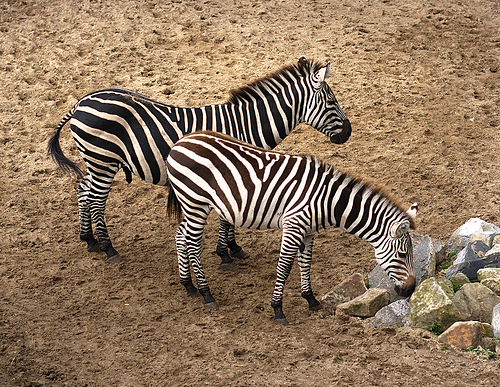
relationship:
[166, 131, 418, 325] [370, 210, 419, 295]
he with head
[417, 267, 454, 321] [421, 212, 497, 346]
moss on rocks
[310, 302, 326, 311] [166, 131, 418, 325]
hoof on he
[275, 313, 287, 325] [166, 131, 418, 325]
hoof on he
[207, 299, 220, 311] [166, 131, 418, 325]
hoof on he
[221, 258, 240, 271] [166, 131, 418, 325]
hoof on he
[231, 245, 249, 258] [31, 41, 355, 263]
hoof on zebra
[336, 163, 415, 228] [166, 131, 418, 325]
mane on he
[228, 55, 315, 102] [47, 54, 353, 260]
mane on zebra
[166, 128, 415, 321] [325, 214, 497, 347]
he looking at rocks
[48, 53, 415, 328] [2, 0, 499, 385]
they standing in field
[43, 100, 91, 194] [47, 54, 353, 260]
tail on zebra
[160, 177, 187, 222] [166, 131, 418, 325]
tail on he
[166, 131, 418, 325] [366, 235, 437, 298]
he smelling rock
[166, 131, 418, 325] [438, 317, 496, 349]
he smelling rock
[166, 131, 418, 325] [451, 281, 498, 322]
he smelling rock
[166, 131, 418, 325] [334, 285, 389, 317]
he smelling rock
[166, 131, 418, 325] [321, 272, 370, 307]
he smelling rock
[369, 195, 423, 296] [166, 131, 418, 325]
head on a he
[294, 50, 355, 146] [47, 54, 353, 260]
head on a zebra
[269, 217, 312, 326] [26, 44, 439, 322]
leg on a zebras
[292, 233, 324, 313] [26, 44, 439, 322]
leg on a zebras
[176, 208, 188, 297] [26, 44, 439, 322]
leg on a zebras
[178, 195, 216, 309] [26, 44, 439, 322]
leg on a zebras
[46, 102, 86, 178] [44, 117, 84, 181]
tail black in color letters